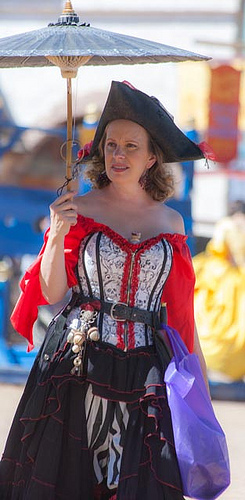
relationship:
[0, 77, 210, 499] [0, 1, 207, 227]
woman holding parisol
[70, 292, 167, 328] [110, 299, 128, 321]
belt with silver buckle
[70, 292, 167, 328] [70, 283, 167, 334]
belt on waist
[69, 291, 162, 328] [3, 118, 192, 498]
belt worn by woman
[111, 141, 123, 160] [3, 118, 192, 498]
nose of woman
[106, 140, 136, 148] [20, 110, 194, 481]
eyes of woman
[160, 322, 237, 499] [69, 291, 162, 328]
bag attached to belt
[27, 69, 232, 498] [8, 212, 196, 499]
woman wearing costume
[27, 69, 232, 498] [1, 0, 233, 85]
woman holding umbrella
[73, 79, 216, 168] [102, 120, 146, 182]
hat on head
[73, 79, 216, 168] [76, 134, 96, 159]
hat with flowers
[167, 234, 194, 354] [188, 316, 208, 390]
red sleeve hanging from arm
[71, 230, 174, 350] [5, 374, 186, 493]
bodice with lace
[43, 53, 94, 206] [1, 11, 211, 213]
bamboo handle on umbrella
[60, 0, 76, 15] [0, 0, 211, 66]
bamboo on umbrella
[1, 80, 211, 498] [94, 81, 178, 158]
girl in hat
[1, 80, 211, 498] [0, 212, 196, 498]
girl dressed in costume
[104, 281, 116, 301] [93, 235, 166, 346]
skull on cloths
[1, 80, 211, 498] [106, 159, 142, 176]
girl has mouth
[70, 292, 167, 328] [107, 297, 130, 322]
belt secured by metal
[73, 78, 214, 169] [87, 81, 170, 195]
hat on head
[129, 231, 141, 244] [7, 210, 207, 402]
bottle out of shirt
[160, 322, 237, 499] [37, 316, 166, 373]
bag attached to hip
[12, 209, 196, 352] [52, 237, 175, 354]
corset on torso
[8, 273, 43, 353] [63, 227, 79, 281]
fabric from sleeve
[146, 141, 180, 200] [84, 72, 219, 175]
hair sticking out of hat